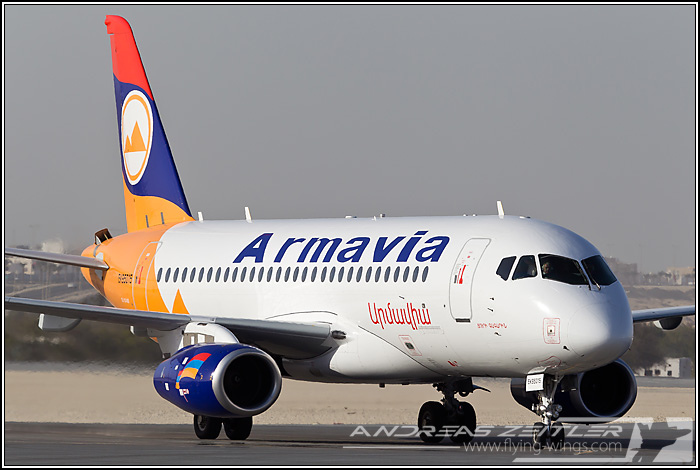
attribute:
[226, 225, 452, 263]
lettering — blue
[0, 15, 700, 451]
plane — white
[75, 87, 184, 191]
logo — white, orange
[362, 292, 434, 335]
writing — red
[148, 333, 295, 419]
engine — blue, orange, red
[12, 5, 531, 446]
airplane — white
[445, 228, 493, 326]
door — white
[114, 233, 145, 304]
door — yellow